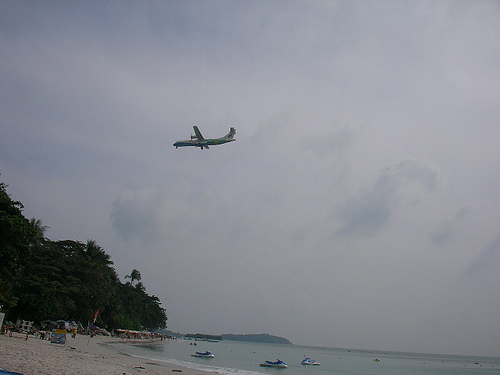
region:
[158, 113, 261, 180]
plane is flying the air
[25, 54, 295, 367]
plane is flying over island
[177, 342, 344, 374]
jet skis in the wayer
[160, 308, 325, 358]
land in the water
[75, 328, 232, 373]
water coming onto beach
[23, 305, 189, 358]
people on the beach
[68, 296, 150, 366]
flag on the beach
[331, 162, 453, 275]
wispy clouds in the sky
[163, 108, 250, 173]
large wings on airplane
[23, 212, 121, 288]
trees have large leaves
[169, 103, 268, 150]
airliner crossing over beach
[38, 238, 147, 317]
tall green trees on beach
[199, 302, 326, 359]
island with mountains in background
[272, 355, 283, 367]
small boats floating in water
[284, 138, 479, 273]
gray clouds in sky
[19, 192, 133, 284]
tall palm trees on beach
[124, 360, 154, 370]
dark seaweed on beach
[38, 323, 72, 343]
yellow and blue sign on beach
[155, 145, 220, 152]
landing gear of plane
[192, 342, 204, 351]
people swimming in water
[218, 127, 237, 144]
the tail of a plane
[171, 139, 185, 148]
the nose of a plane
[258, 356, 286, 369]
a blue and white jet ski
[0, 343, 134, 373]
a patch of sandy beach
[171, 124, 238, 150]
an airplane flying in the sky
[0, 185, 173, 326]
a group of green trees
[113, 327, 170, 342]
people on the beach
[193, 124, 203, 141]
the wing of a plane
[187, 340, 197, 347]
people in the ocean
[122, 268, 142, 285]
the top of a palm tree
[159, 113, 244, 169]
airplane in the sky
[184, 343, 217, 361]
jet ski in the ocean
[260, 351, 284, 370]
jet ski in the ocean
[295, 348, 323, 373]
jet ski in the ocean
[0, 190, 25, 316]
tree along the shore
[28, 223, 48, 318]
tree along the shore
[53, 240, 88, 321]
tree along the shore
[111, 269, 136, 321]
tree along the shore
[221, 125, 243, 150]
tail of the plane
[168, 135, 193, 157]
nose of the plane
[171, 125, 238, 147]
a big airplane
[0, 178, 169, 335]
a bunch of leafy green trees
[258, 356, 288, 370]
a white and blue jet ski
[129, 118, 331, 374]
a plane flying over a beach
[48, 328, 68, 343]
a sign on the beach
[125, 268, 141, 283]
a tall palm tree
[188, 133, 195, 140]
a plane perpeller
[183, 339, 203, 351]
people in the ocean